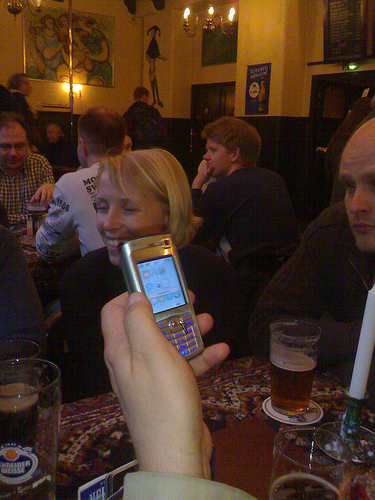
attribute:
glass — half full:
[263, 315, 326, 423]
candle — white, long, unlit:
[350, 279, 373, 399]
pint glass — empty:
[5, 362, 67, 496]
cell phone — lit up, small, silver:
[117, 230, 207, 368]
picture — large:
[20, 10, 118, 86]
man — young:
[192, 117, 290, 230]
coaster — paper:
[259, 391, 329, 432]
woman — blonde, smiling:
[88, 150, 202, 277]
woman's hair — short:
[115, 149, 215, 247]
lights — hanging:
[179, 6, 248, 45]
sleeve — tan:
[113, 467, 259, 498]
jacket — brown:
[256, 205, 372, 365]